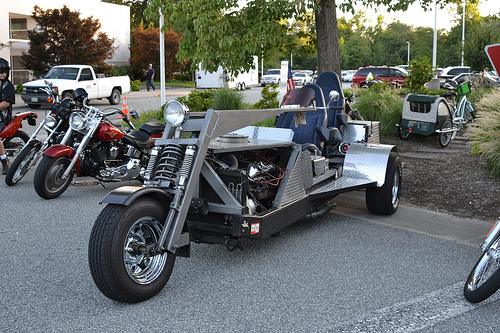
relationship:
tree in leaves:
[99, 0, 478, 86] [118, 0, 476, 79]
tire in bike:
[89, 197, 176, 304] [86, 63, 430, 306]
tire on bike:
[361, 147, 406, 215] [1, 108, 38, 178]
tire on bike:
[88, 197, 177, 304] [86, 63, 430, 306]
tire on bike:
[2, 139, 43, 189] [2, 82, 106, 190]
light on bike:
[153, 97, 191, 131] [80, 52, 423, 313]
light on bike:
[69, 111, 88, 131] [34, 96, 164, 199]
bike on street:
[86, 71, 403, 303] [0, 155, 499, 332]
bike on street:
[32, 87, 166, 199] [3, 87, 496, 331]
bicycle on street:
[395, 70, 480, 147] [3, 87, 496, 331]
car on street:
[350, 65, 414, 89] [3, 87, 496, 331]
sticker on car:
[67, 65, 103, 91] [54, 38, 162, 96]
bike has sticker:
[86, 71, 403, 303] [247, 213, 272, 249]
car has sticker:
[299, 44, 496, 128] [338, 60, 418, 92]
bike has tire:
[86, 71, 403, 303] [362, 154, 406, 214]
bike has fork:
[22, 61, 155, 216] [61, 99, 101, 180]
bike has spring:
[86, 71, 403, 303] [153, 141, 180, 190]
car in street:
[18, 65, 131, 110] [3, 87, 496, 331]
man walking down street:
[145, 62, 157, 91] [5, 85, 312, 116]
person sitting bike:
[0, 55, 17, 168] [0, 110, 38, 163]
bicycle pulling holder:
[391, 66, 486, 150] [391, 92, 458, 146]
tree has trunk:
[331, 17, 451, 101] [306, 10, 349, 60]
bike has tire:
[32, 87, 166, 199] [460, 227, 498, 307]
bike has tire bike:
[7, 85, 70, 185] [7, 132, 38, 184]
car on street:
[350, 65, 414, 89] [4, 83, 383, 109]